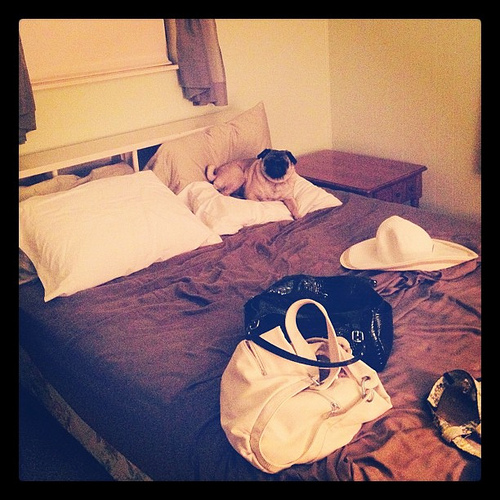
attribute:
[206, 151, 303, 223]
pug — laying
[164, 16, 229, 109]
curtain — open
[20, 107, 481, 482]
bed — a, brown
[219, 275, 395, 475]
purses — white, black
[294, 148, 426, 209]
table — wooden, brown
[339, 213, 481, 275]
hat — white, frumpy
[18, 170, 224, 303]
pillow — white, rectangular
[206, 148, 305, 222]
dog — white, brown, laying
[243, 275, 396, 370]
purse — black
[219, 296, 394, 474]
purse — white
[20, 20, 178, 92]
shades — down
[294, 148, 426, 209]
stand — wooden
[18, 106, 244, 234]
bookshelf — headboard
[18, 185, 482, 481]
blanket — brown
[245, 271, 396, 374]
bag — shiny